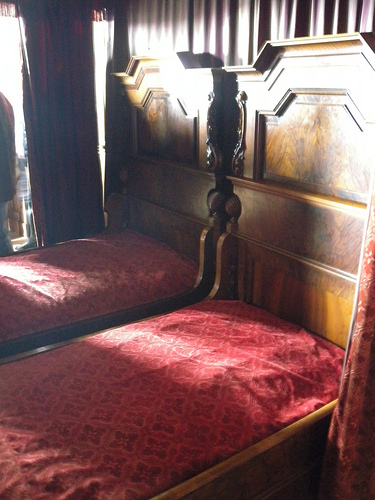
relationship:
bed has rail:
[0, 51, 216, 372] [0, 245, 205, 368]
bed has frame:
[0, 30, 373, 498] [156, 395, 342, 499]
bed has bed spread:
[0, 30, 373, 498] [1, 225, 343, 498]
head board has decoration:
[97, 33, 374, 340] [200, 95, 264, 240]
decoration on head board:
[200, 95, 264, 240] [97, 33, 374, 340]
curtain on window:
[12, 3, 106, 244] [0, 1, 111, 246]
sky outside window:
[0, 17, 25, 99] [0, 1, 111, 246]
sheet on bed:
[0, 303, 349, 500] [0, 30, 373, 498]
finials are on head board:
[194, 67, 245, 302] [97, 33, 374, 340]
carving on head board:
[202, 97, 249, 175] [97, 33, 374, 340]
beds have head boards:
[0, 30, 373, 498] [97, 33, 374, 340]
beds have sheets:
[0, 30, 373, 498] [0, 303, 349, 500]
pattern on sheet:
[1, 225, 343, 498] [0, 303, 349, 500]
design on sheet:
[1, 225, 343, 498] [0, 303, 349, 500]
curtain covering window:
[12, 3, 106, 244] [0, 1, 111, 246]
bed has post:
[0, 226, 220, 357] [195, 69, 219, 286]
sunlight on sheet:
[0, 258, 66, 300] [0, 226, 220, 357]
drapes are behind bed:
[105, 1, 374, 69] [0, 30, 373, 498]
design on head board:
[241, 77, 367, 212] [219, 30, 371, 346]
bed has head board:
[0, 30, 373, 498] [219, 30, 371, 346]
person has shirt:
[0, 92, 34, 258] [3, 90, 19, 202]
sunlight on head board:
[141, 51, 221, 122] [105, 53, 211, 270]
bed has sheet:
[0, 51, 216, 372] [0, 226, 220, 357]